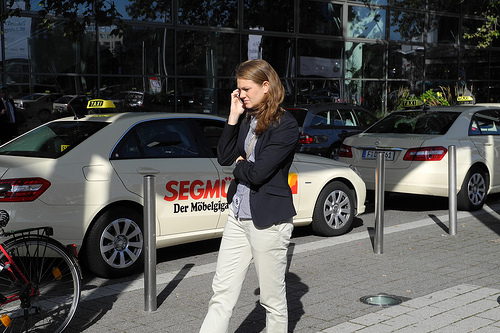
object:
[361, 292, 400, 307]
light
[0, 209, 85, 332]
bicycle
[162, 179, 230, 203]
text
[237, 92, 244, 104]
cell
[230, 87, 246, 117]
hand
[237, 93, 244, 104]
cell phone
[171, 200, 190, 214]
word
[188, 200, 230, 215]
word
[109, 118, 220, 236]
door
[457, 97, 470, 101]
sign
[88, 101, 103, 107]
sign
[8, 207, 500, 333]
sidewalk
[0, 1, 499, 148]
reflection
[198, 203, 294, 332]
pants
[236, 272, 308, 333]
shadow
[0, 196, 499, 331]
ground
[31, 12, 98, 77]
window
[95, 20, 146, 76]
window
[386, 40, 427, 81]
window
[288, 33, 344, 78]
window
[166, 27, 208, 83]
window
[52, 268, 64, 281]
reflector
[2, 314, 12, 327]
reflector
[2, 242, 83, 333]
spokes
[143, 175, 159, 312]
pole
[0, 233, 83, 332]
tire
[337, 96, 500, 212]
cars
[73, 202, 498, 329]
concrete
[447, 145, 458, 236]
poles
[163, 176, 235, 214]
company name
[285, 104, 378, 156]
car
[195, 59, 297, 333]
woman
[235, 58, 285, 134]
hair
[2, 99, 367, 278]
car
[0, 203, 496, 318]
curb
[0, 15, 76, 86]
windows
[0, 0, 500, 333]
street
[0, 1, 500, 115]
building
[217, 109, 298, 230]
blazer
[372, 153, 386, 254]
pole